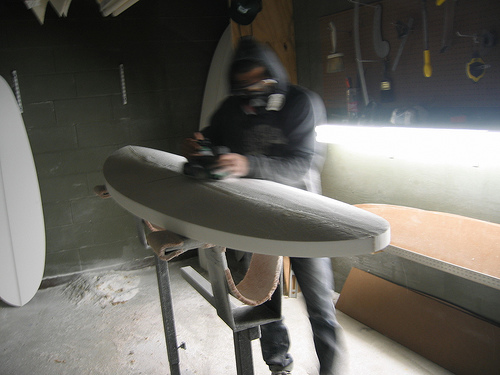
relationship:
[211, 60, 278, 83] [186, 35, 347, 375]
eyes on jacket man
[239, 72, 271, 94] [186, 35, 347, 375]
nose on jacket man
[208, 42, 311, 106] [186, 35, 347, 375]
head on jacket man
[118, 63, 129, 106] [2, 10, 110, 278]
metal strip on block wall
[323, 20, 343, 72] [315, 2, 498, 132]
tool hanging on wall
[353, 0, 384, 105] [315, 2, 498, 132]
tool hanging on wall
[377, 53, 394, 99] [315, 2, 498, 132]
tool hanging on wall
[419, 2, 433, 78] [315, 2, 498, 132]
tool hanging on wall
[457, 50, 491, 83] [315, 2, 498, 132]
tool hanging on wall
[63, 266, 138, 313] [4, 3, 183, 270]
dust near wall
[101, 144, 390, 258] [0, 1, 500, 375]
surfboard in room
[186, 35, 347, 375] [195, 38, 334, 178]
jacket man wearing black sweater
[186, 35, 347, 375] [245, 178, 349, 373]
jacket man wearing pants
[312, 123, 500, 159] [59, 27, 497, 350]
light lighting room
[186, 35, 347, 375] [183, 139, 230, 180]
jacket man holding electric sander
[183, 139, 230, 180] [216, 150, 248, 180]
electric sander in hands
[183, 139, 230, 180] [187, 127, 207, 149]
electric sander in hands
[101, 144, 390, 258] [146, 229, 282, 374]
surfboard on frame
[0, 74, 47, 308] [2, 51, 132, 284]
surfboard on wall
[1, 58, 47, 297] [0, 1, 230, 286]
surfboard on wall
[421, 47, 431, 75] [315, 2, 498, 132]
handle hanging on wall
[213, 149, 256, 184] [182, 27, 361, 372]
hand on man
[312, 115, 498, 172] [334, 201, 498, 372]
light above work area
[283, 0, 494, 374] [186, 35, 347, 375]
work area behind jacket man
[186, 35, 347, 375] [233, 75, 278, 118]
jacket man wearing protective mask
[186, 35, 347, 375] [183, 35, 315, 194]
jacket man wearing black hoodie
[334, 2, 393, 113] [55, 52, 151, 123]
tool on wall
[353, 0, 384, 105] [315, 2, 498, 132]
tool on wall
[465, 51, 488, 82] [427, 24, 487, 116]
tool on wall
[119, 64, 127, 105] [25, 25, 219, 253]
metal strip on wall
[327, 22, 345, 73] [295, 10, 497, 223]
tool on wall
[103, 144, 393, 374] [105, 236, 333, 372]
surfboard on frame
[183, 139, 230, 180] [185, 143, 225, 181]
electric sander holding sander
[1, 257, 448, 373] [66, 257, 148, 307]
floor covered with dust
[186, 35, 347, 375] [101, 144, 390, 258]
jacket man working on surfboard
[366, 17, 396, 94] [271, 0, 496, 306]
tool hanging on wall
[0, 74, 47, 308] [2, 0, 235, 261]
surfboard leaning against wall